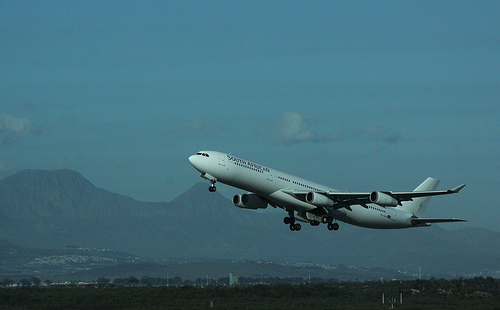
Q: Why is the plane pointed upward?
A: It is taking off.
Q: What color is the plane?
A: White.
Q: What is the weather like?
A: Hazy.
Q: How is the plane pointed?
A: Upward.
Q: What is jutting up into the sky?
A: Mountains.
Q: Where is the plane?
A: In the air.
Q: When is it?
A: Daytime.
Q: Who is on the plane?
A: Passengers.